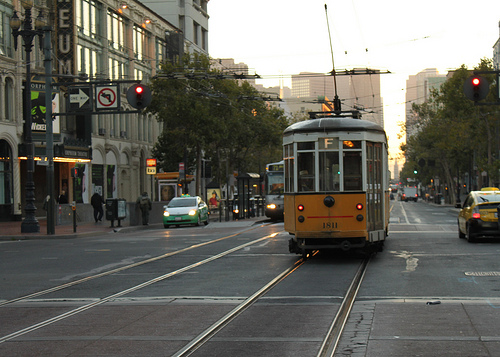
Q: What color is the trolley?
A: Yellow and white.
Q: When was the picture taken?
A: During the day.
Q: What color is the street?
A: Black.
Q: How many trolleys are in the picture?
A: One.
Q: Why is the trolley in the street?
A: It is moving on the tracks.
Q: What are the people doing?
A: Walking.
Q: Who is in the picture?
A: People walking on the sidewalk.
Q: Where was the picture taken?
A: Downtown.